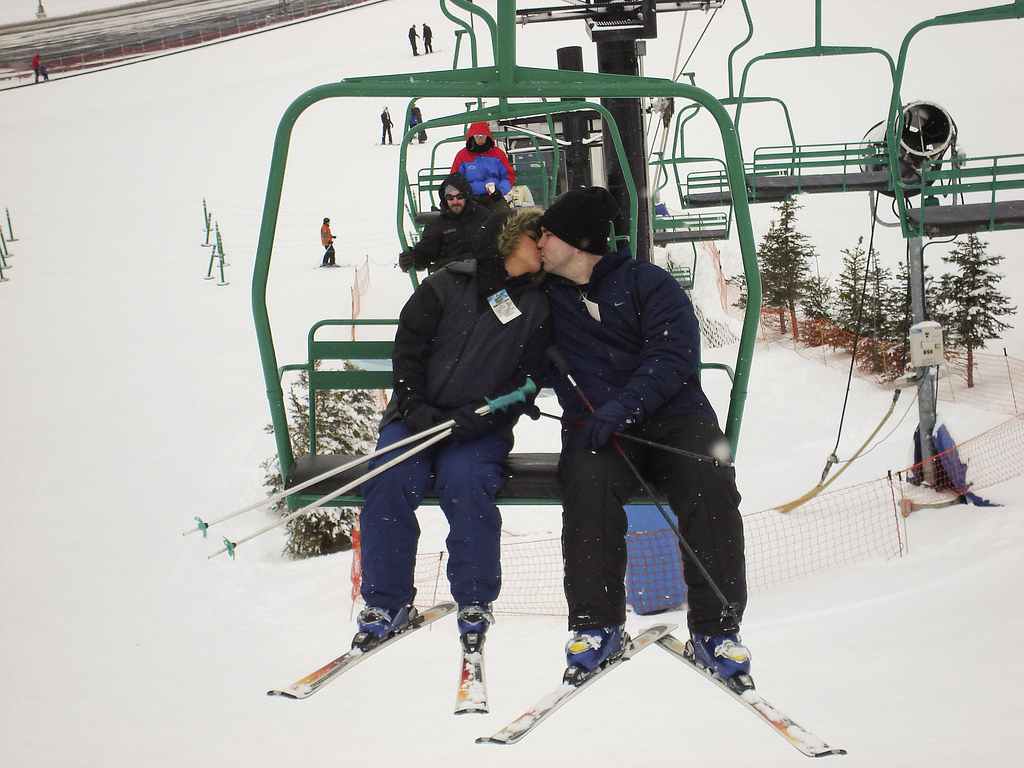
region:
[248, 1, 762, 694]
two people kissing on a ski lift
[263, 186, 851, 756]
two people wearing skis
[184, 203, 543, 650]
woman holding green and silver ski poles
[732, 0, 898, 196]
an empty green ski lift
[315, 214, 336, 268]
man standing on the snow wearing orange jacket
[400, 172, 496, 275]
man wearing a black coat with a black hood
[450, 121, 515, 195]
man wearing a red and blue coat with a hood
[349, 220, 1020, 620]
an orange fence on the snow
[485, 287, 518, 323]
a white and blue sticker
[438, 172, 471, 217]
black sunglasses on man's face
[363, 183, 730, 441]
a couple is kissing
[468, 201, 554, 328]
the woman is blonde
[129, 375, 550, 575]
snow poles are color silver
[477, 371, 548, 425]
dandles of snow poles are green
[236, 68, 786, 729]
a couple sit in a snow lift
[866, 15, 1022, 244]
bench of a snow lift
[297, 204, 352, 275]
person on the snow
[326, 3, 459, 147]
people in a hill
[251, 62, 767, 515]
Green ski lift chair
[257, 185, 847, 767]
Couple kissing in ski lift chair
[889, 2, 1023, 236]
Green ski lift chair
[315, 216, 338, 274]
Person wearing orange jacket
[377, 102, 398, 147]
Person skiing on ski slope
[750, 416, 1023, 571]
Orange fence separating ski slopes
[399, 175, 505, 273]
Person in black jacket on ski lift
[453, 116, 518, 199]
Person wearing red and blue jacket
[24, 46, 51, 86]
Person skiing on ski slope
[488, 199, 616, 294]
the kissing couple's heads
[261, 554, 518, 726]
The girl's skis from the kissing couple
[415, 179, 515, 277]
the guy in the black coat behind the couple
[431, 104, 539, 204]
the person in the red and blue jackey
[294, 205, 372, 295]
The person in the orange jacket skiing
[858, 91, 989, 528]
The pole with the big circle thing on it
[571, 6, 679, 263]
The first ski lift pole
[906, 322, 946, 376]
The white box on the silver pole